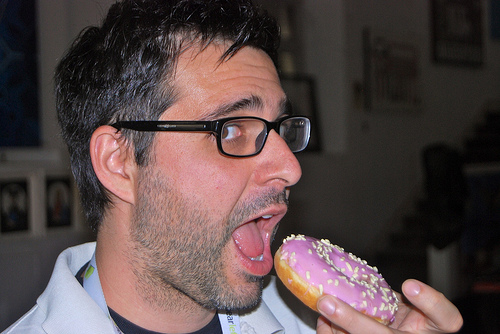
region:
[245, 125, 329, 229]
man has pointed nose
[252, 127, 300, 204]
man has pointed nose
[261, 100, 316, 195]
man has pointed nose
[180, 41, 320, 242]
man has pointed nose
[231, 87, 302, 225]
man has pointed nose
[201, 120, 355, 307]
man has pointed nose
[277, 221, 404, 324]
Doughnut with pink glaze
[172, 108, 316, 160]
glasses on man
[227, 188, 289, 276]
Man with mouth open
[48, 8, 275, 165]
Man with black hair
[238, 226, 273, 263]
Man with tongue hanging out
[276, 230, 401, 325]
Doughnut with sprinkles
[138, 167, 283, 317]
man with scratchy beard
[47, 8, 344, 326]
Man looking at the camera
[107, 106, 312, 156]
man wearing black glasses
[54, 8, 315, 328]
man eating glazed doughnut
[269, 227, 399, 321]
a donut with frosting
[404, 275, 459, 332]
a man's finger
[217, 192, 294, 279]
an open mouth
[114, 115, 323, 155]
a man's dark-rimmed glasses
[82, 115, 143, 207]
a man's hear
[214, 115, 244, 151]
a man's eye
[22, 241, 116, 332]
the white collar of a man's shirt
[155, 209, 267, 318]
a scruffy beard on a man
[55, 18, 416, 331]
the head of a man about to eat a donut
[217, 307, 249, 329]
a name on the collar of a shirt